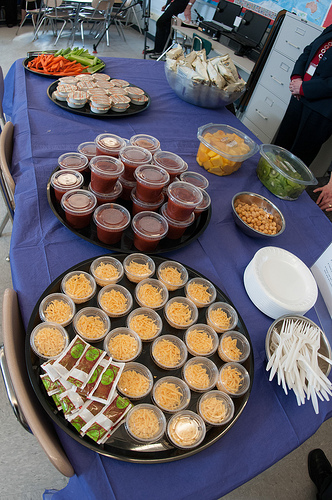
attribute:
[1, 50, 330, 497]
table cover — blue 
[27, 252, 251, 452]
cheese cups — portable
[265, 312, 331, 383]
bowl — metal, silver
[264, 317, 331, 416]
forks — disposable, white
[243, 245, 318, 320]
plates — styrofoam , stacked, small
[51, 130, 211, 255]
sauce — portable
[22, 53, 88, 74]
carrots — piled, crisp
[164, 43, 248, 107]
snacks — unknown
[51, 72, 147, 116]
dip — unknown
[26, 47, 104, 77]
veggies — served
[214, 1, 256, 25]
headphones — hanging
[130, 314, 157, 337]
cheese — orange, cubed, shredded